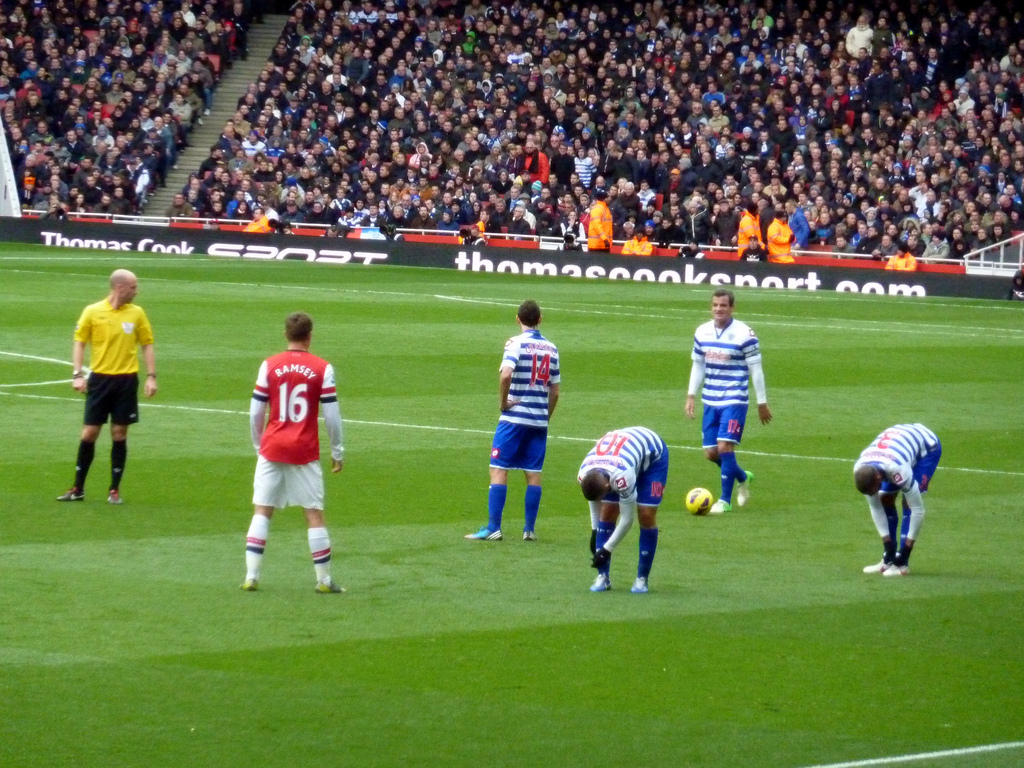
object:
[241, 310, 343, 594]
men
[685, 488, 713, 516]
soccerball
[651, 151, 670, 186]
person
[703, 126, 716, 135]
person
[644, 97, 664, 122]
person